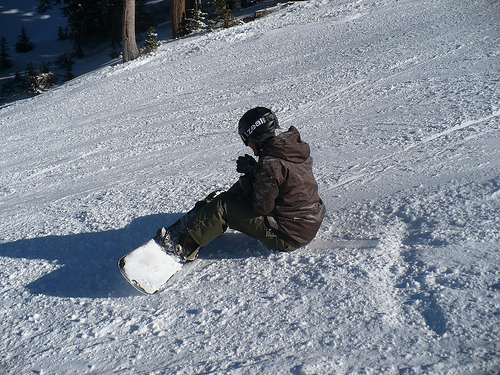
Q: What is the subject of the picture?
A: Snowboarder.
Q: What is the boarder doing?
A: Sitting.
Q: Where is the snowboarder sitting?
A: On the ground.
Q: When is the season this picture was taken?
A: Winter.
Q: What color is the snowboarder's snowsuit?
A: Brown.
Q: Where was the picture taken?
A: Ski hill.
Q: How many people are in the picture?
A: One.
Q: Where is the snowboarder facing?
A: Downhill.